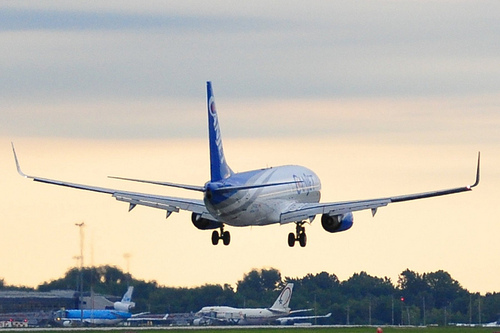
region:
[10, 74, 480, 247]
a plane taking off into the air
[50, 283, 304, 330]
two parked planes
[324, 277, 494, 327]
a row of trees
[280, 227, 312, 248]
wheels on a air plane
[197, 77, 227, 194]
the blue tail wing on a plane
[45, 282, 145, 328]
a parked blue and white plane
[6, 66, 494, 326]
plane ready to land at airport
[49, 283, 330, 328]
blue and silver airplanes on ground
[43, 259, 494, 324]
trees behind planes and fencing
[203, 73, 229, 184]
blue and white tail on plane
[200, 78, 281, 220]
gray swirls under blue on tail and body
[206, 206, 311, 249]
black wheels under plane's body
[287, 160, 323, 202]
logo and name of company on plane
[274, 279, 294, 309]
red circle and blue star on plane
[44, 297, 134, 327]
solid blue over silver on plane body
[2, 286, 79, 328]
flat and dark building behind front of plane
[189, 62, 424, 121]
A cloudy unique sky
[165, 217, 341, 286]
THe plane has wheels out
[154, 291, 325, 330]
A plane on the ground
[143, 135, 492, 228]
The plane is trying to land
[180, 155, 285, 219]
It has a light blue ending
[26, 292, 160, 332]
A blue plane on the ground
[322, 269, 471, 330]
Plentiful trees in the background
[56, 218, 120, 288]
Towers to help planes land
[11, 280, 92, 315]
Part of the airport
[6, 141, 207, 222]
The large wing of the plane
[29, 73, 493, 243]
plane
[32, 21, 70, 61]
white clouds n blue sky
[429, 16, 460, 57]
white clouds n blue sky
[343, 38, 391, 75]
white clouds n blue sky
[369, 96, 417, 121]
white clouds n blue sky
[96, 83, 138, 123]
white clouds n blue sky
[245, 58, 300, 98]
white clouds n blue sky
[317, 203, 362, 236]
Engine on wing of airplane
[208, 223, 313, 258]
Airplane landing gear down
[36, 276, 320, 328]
Planes on airport runway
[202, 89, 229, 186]
Airline name on tail of airplane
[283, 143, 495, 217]
Right wing of airplane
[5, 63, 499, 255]
Airplane flying close to the ground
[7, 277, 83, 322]
Airport storage building beside runway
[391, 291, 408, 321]
Marker flag beside airport runway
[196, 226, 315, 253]
wheels on a plane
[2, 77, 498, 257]
a plane in the sky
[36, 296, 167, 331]
a blue and white plane